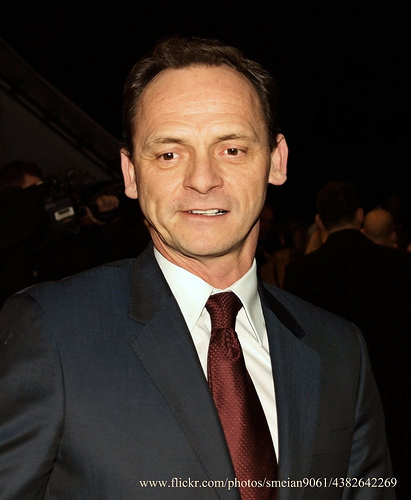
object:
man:
[2, 36, 397, 500]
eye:
[154, 147, 182, 162]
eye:
[220, 146, 250, 159]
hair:
[119, 34, 279, 151]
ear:
[119, 146, 141, 204]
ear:
[269, 130, 291, 188]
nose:
[183, 153, 224, 193]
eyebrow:
[214, 129, 255, 148]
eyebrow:
[141, 135, 184, 151]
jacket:
[0, 242, 397, 497]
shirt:
[147, 253, 285, 470]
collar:
[149, 248, 270, 350]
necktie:
[203, 293, 284, 500]